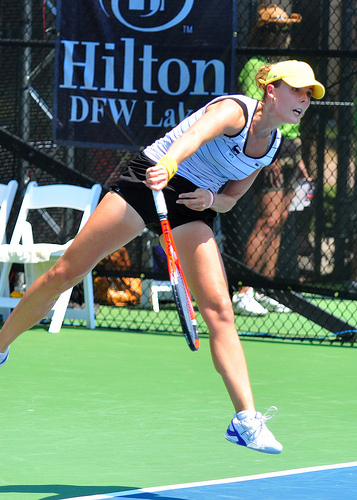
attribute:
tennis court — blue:
[120, 458, 351, 499]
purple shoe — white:
[200, 401, 293, 464]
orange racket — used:
[128, 159, 219, 364]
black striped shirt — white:
[88, 98, 293, 209]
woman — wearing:
[22, 79, 326, 409]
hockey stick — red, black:
[136, 153, 249, 348]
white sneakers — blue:
[221, 400, 288, 467]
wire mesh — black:
[16, 21, 355, 345]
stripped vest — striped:
[77, 65, 301, 215]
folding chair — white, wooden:
[5, 183, 112, 327]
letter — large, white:
[59, 38, 100, 91]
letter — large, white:
[98, 40, 118, 91]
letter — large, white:
[119, 35, 137, 92]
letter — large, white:
[137, 42, 159, 93]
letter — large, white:
[157, 57, 192, 96]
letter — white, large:
[68, 96, 90, 123]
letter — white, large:
[89, 95, 108, 123]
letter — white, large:
[106, 96, 137, 125]